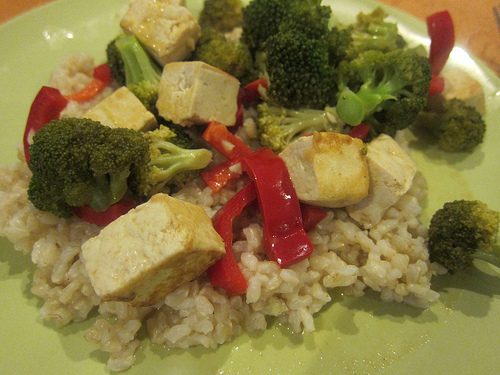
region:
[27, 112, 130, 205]
this is broccoli on the plate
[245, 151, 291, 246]
this is tomato in the plate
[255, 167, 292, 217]
the tomato is red in color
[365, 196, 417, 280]
this is rice fried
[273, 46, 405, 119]
the broccoli is cooked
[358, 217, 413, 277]
the rice is white in color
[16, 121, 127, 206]
the broccoli is green in color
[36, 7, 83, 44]
this is the plate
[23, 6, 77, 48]
the plate is green in color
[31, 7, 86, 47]
the plate is round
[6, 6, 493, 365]
food on a round plate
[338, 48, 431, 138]
cooked green brocolli floret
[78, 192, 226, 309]
cubed shaped piece of chicken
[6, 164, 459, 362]
white rice on plate under stir fry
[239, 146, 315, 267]
thin slice of cooked red pepper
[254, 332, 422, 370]
sauce on the plate under stir fry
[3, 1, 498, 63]
plate is on a wooden table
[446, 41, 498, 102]
light reflecting on edge of plate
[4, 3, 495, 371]
round green plate sitting on the table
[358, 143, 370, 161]
small piece of broccoli on chicken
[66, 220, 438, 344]
Rice on the plate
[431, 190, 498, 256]
A piece of broccoli near the rice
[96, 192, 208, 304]
Chicken on top of the rice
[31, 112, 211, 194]
A piece of broccoli by the chicken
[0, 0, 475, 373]
A plate full of food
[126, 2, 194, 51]
The chicken has sauce on it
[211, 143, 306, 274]
A tomato on the rice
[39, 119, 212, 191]
The broccoli on a tomato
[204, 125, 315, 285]
The tomato has been sliced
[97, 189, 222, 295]
The chicken comes in cube form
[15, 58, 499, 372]
rice on a plate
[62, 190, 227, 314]
chicken on the rice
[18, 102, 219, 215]
broccoli on the rice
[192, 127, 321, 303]
peppers on the rice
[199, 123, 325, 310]
the peppers are red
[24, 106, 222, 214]
the broccoli is green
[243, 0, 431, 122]
this broccoli is dark green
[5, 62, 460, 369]
the rice is white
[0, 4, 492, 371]
the plate is green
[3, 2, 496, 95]
an orange surface behind the plate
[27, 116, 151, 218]
piece of dark green cooked broccoli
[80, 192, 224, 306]
cube of fried tofu is beige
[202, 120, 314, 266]
strip of cooked red pepper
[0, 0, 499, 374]
lime green plate with rice and vegetables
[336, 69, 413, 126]
light green cooked broccoli stalk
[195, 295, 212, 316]
grain of cooked white rice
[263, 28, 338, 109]
dark green piece of cooked broccoli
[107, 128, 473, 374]
oily residue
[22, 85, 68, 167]
underside of cooked red pepper piece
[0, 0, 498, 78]
brown table made of wood